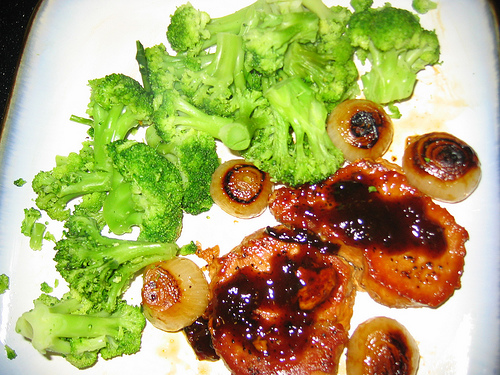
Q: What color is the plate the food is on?
A: White.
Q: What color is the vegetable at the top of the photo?
A: Green.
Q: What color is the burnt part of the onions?
A: Black.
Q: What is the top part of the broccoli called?
A: Crown.